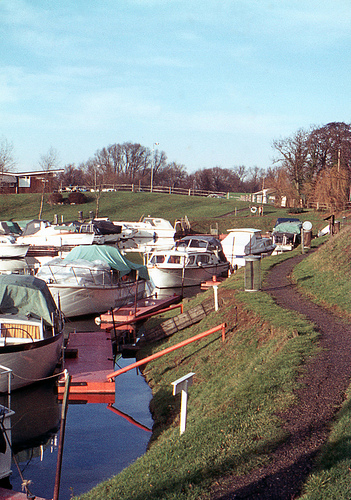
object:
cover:
[63, 244, 155, 293]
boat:
[142, 236, 231, 288]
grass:
[2, 190, 351, 497]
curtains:
[0, 322, 42, 341]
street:
[195, 242, 348, 497]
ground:
[4, 191, 350, 498]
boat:
[111, 216, 176, 238]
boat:
[16, 220, 96, 254]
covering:
[0, 271, 59, 326]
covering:
[271, 218, 303, 236]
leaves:
[269, 137, 283, 147]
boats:
[0, 275, 59, 395]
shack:
[0, 168, 65, 194]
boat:
[271, 218, 301, 256]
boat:
[34, 245, 148, 319]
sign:
[250, 206, 257, 213]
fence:
[54, 184, 351, 212]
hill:
[0, 191, 325, 234]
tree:
[60, 120, 350, 214]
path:
[201, 243, 331, 500]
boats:
[0, 218, 30, 257]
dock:
[58, 331, 115, 405]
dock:
[100, 293, 184, 334]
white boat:
[219, 228, 276, 269]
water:
[0, 333, 154, 500]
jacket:
[259, 208, 261, 213]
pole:
[261, 207, 263, 217]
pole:
[213, 286, 218, 311]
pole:
[301, 228, 305, 254]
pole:
[53, 373, 71, 499]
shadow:
[123, 389, 350, 495]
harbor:
[0, 218, 310, 500]